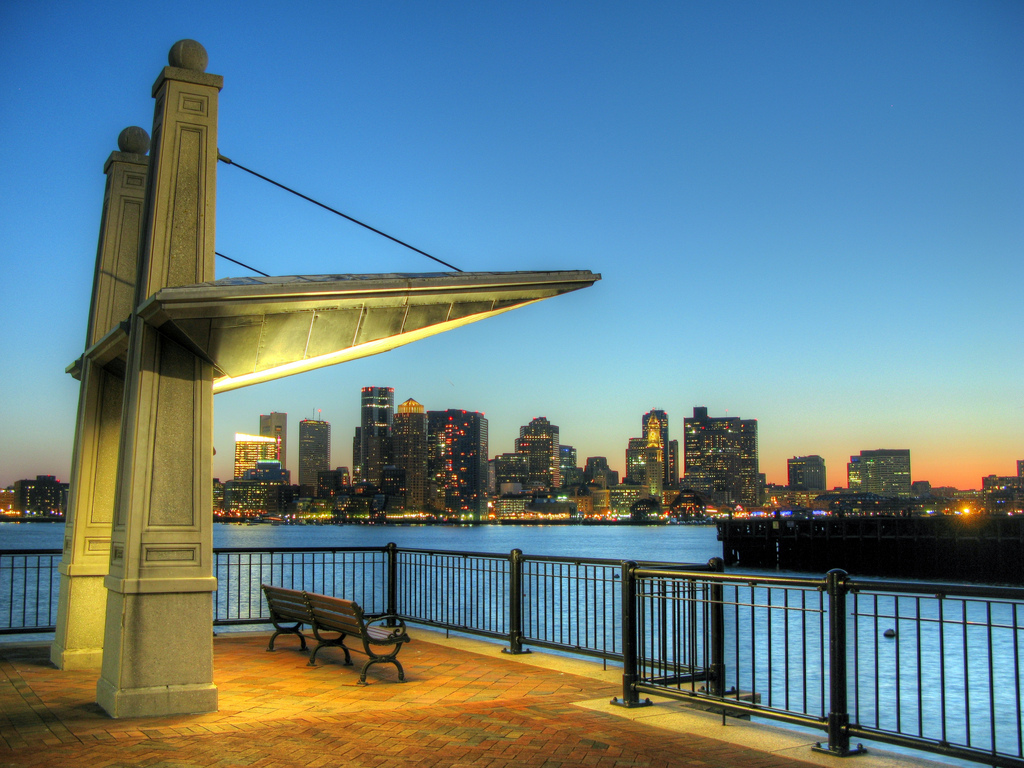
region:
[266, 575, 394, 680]
The bench overlooking the river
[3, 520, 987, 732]
the metal railing around the area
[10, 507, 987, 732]
the calm blue river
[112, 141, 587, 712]
the unique covered structure over the bench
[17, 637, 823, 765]
the bricks on the ground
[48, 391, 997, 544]
the skyscrapers in the distancer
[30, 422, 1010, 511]
the pinkish orange skyline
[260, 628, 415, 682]
the feet of the bench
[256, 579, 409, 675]
wooden bench in a dock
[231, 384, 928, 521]
a bunch of buildings in the background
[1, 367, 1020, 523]
big city in the background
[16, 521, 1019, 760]
calm light blue water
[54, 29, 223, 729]
concrete columns on a dock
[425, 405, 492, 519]
dark building with red lights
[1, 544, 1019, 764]
black rails on a dock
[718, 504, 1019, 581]
dark boat on calm water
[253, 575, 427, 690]
benches by a waterway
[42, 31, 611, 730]
a structure with a light in it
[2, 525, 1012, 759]
guardrail in front of water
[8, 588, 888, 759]
concrete area by water for viewing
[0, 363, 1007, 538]
cityscape in the distance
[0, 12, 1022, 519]
sunset sky just as the sun is going down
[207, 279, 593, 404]
light emanating from a structure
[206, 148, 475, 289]
wires holding a heavy looking light structure up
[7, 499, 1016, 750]
a large area of water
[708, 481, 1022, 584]
a dark ship or other area by water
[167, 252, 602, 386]
a awning over a pier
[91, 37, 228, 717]
a stone pillar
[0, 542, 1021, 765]
a black fence at a pier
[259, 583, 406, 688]
a black and wood bench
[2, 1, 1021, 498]
a blue sky at dusk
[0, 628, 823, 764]
a brick covered ground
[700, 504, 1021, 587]
a large ship in the water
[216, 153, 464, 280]
a metal rope holding an awning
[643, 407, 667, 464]
a high rise in a city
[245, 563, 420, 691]
THIS IS A BENCH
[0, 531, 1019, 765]
THE WATER IS BLUE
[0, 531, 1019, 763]
THIS IS A GUARD RAIL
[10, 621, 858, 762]
THE SIDEWALK IS BRICK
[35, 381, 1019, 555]
THE SKYLINE IS BRIGHT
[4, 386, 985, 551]
THIS IS A SKYLINE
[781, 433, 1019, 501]
THE SUN IS SETTING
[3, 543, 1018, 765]
the railing is made of metal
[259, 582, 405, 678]
a bench is facing the city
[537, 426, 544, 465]
a window on the building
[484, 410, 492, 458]
a window on the building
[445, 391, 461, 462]
a window on the building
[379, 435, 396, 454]
a window on the building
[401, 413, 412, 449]
a window on the building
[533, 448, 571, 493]
a window on the building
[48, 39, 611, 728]
a large structure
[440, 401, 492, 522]
one building in the distance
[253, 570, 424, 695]
a bench on the ground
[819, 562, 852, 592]
the top of a fence post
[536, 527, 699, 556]
water just above the fence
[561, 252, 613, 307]
the very tip of the roof of the structure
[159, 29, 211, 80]
the ball top of the structure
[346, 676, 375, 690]
bottom foot of the bench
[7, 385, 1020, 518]
all of the buildings in the distance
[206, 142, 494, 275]
the support wire of the structure